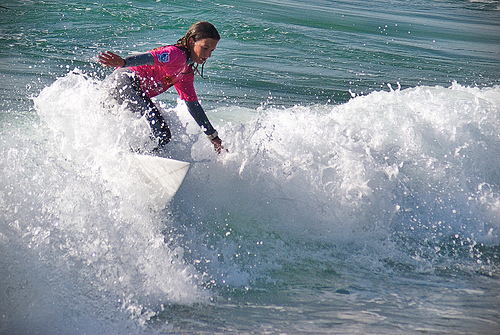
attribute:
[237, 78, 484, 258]
splash — huge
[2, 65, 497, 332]
splash — huge, big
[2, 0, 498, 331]
water — blue, blue green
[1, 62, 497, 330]
waves — white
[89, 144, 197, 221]
surfboard — white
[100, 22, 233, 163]
person — wet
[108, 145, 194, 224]
surfboard — pink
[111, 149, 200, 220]
surfboard — white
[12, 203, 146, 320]
water — white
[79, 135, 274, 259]
surfboard — white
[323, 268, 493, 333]
water — gray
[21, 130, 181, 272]
wave — white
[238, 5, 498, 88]
water — bluish green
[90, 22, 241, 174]
surfer — a girl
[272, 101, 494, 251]
wave — rising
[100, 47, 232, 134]
shirt — pink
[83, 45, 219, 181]
wetsuit — grey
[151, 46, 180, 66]
logo — blue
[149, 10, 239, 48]
hair — brown